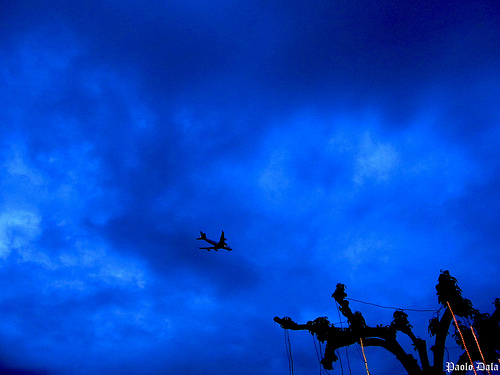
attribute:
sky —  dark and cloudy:
[283, 100, 433, 170]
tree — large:
[261, 273, 485, 358]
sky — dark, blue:
[6, 8, 485, 216]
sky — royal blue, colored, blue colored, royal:
[11, 19, 485, 206]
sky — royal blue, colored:
[15, 9, 485, 196]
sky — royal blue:
[2, 0, 497, 373]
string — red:
[443, 298, 476, 371]